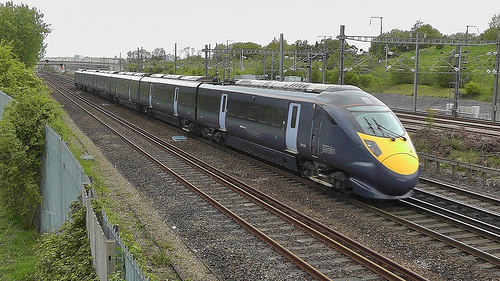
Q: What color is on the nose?
A: Yellow.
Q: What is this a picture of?
A: A fast train.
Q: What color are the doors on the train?
A: White.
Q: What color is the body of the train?
A: Black.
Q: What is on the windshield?
A: Wipers.